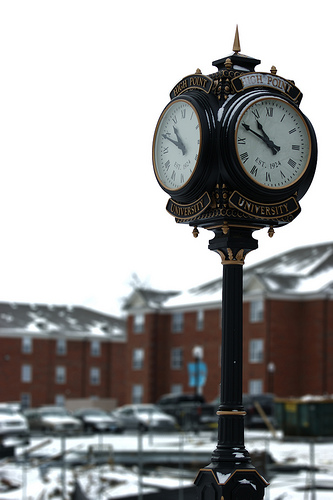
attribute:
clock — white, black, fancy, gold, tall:
[229, 86, 320, 191]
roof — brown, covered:
[195, 245, 324, 322]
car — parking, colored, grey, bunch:
[43, 358, 248, 441]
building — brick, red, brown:
[112, 315, 236, 371]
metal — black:
[189, 268, 255, 414]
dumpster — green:
[279, 367, 329, 426]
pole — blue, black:
[177, 220, 291, 450]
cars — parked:
[0, 366, 270, 464]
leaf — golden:
[217, 228, 269, 273]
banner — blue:
[173, 351, 231, 402]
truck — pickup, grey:
[5, 392, 45, 446]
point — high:
[198, 66, 304, 211]